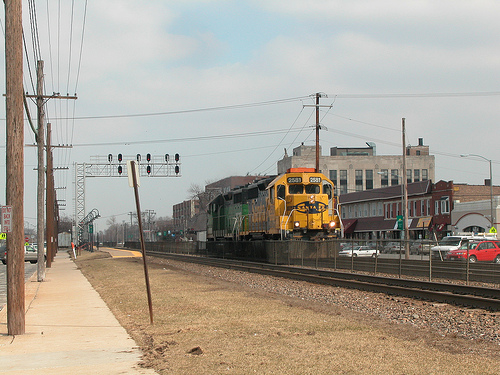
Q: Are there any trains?
A: Yes, there is a train.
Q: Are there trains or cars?
A: Yes, there is a train.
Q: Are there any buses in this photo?
A: No, there are no buses.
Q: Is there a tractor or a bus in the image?
A: No, there are no buses or tractors.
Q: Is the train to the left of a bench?
A: No, the train is to the left of the car.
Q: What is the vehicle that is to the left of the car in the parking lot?
A: The vehicle is a train.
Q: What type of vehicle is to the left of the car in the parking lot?
A: The vehicle is a train.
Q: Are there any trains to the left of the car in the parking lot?
A: Yes, there is a train to the left of the car.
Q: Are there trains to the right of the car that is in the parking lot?
A: No, the train is to the left of the car.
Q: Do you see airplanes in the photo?
A: No, there are no airplanes.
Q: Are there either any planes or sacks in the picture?
A: No, there are no planes or sacks.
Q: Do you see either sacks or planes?
A: No, there are no planes or sacks.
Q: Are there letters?
A: Yes, there are letters.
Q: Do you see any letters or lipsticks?
A: Yes, there are letters.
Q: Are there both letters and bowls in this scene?
A: No, there are letters but no bowls.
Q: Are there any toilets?
A: No, there are no toilets.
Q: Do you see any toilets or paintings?
A: No, there are no toilets or paintings.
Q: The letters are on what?
A: The letters are on the pole.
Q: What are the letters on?
A: The letters are on the pole.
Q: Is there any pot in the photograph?
A: No, there are no pots.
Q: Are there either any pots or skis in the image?
A: No, there are no pots or skis.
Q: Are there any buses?
A: No, there are no buses.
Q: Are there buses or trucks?
A: No, there are no buses or trucks.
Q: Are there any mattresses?
A: No, there are no mattresses.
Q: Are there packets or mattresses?
A: No, there are no mattresses or packets.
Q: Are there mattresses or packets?
A: No, there are no mattresses or packets.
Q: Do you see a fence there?
A: Yes, there is a fence.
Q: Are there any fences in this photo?
A: Yes, there is a fence.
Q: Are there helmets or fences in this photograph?
A: Yes, there is a fence.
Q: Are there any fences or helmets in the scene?
A: Yes, there is a fence.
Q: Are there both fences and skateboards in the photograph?
A: No, there is a fence but no skateboards.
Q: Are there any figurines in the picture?
A: No, there are no figurines.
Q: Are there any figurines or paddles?
A: No, there are no figurines or paddles.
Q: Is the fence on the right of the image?
A: Yes, the fence is on the right of the image.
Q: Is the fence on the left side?
A: No, the fence is on the right of the image.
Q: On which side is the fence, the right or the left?
A: The fence is on the right of the image.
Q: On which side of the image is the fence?
A: The fence is on the right of the image.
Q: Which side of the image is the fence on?
A: The fence is on the right of the image.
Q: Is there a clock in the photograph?
A: No, there are no clocks.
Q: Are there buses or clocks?
A: No, there are no clocks or buses.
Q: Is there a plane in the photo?
A: No, there are no airplanes.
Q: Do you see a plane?
A: No, there are no airplanes.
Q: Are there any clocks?
A: No, there are no clocks.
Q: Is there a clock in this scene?
A: No, there are no clocks.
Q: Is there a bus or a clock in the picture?
A: No, there are no clocks or buses.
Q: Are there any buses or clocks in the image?
A: No, there are no clocks or buses.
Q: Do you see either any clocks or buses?
A: No, there are no clocks or buses.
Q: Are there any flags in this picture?
A: No, there are no flags.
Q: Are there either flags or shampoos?
A: No, there are no flags or shampoos.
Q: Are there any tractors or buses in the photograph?
A: No, there are no buses or tractors.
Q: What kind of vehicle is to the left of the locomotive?
A: The vehicles are cars.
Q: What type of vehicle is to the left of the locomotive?
A: The vehicles are cars.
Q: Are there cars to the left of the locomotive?
A: Yes, there are cars to the left of the locomotive.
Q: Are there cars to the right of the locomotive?
A: No, the cars are to the left of the locomotive.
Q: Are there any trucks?
A: No, there are no trucks.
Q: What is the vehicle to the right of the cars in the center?
A: The vehicle is a locomotive.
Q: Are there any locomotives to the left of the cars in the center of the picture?
A: No, the locomotive is to the right of the cars.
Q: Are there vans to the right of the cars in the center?
A: No, there is a locomotive to the right of the cars.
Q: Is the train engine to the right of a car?
A: No, the train engine is to the left of a car.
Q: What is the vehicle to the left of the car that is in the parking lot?
A: The vehicle is a locomotive.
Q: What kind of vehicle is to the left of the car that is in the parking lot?
A: The vehicle is a locomotive.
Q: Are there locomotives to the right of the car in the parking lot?
A: No, the locomotive is to the left of the car.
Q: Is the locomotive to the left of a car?
A: Yes, the locomotive is to the left of a car.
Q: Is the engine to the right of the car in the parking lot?
A: No, the engine is to the left of the car.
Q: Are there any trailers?
A: No, there are no trailers.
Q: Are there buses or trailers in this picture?
A: No, there are no trailers or buses.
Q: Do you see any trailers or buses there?
A: No, there are no trailers or buses.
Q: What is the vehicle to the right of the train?
A: The vehicle is a car.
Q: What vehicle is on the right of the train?
A: The vehicle is a car.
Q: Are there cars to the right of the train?
A: Yes, there is a car to the right of the train.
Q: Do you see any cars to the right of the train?
A: Yes, there is a car to the right of the train.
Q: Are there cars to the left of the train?
A: No, the car is to the right of the train.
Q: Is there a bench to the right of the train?
A: No, there is a car to the right of the train.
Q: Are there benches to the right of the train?
A: No, there is a car to the right of the train.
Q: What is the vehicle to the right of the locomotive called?
A: The vehicle is a car.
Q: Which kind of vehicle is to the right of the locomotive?
A: The vehicle is a car.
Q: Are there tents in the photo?
A: No, there are no tents.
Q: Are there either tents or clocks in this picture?
A: No, there are no tents or clocks.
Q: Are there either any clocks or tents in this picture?
A: No, there are no tents or clocks.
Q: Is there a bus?
A: No, there are no buses.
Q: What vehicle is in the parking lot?
A: The vehicle is a car.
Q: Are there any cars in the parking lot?
A: Yes, there is a car in the parking lot.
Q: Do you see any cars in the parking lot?
A: Yes, there is a car in the parking lot.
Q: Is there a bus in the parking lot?
A: No, there is a car in the parking lot.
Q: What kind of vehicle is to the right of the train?
A: The vehicle is a car.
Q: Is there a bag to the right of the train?
A: No, there is a car to the right of the train.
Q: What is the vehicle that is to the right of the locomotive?
A: The vehicle is a car.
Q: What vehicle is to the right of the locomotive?
A: The vehicle is a car.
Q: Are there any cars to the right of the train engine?
A: Yes, there is a car to the right of the train engine.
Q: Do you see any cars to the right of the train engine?
A: Yes, there is a car to the right of the train engine.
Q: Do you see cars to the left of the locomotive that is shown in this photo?
A: No, the car is to the right of the locomotive.